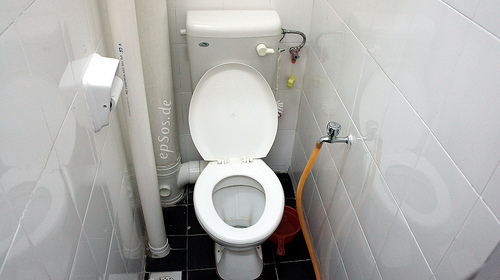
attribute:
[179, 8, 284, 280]
toilet — white, labelled, new, plastic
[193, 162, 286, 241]
seat — white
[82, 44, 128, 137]
holder — white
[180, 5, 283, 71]
tank — white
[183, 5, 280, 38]
cover — white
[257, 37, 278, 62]
handle — white, plastic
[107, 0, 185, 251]
pipe — white, tall, long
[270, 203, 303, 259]
pan — red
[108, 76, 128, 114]
tissue — white, new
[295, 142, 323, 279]
hose — orange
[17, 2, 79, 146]
tile — white, square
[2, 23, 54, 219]
tile — white, square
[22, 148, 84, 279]
tile — square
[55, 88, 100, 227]
tile — square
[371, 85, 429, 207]
tile — white, square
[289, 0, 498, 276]
wall — tile, shiny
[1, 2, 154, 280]
wall — tile, white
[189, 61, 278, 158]
lid — up, plastic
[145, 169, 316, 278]
floor — tile, black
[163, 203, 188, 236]
tile — black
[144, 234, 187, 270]
tile — black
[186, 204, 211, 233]
tile — black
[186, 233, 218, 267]
tile — black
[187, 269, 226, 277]
tile — black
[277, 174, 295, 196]
tile — black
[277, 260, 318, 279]
tile — black